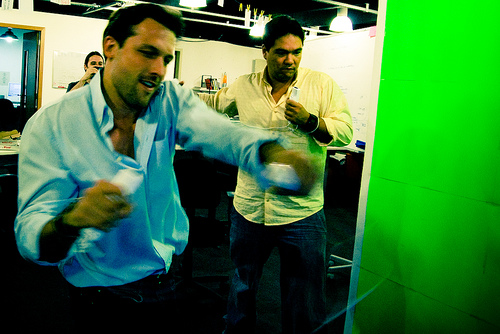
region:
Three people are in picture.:
[46, 15, 371, 237]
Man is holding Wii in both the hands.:
[108, 115, 300, 220]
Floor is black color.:
[332, 254, 348, 331]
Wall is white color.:
[326, 51, 376, 83]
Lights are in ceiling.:
[176, 0, 368, 44]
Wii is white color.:
[99, 156, 309, 216]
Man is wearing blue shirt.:
[39, 89, 209, 259]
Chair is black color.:
[1, 171, 23, 241]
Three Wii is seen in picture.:
[71, 86, 336, 209]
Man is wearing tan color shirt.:
[196, 70, 344, 230]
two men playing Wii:
[12, 7, 372, 329]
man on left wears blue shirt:
[11, 7, 306, 332]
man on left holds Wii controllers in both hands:
[13, 10, 330, 286]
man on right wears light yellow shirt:
[210, 22, 347, 219]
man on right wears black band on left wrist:
[208, 12, 357, 166]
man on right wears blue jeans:
[205, 7, 328, 327]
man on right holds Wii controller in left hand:
[196, 16, 362, 166]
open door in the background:
[0, 0, 55, 127]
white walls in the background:
[10, 13, 374, 163]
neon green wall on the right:
[342, 8, 487, 330]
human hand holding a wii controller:
[253, 136, 315, 198]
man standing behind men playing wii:
[54, 41, 104, 95]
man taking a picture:
[61, 46, 106, 98]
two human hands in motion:
[59, 144, 329, 234]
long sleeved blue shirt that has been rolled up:
[11, 81, 310, 299]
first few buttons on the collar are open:
[96, 113, 158, 180]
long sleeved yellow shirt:
[188, 70, 353, 240]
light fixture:
[328, 11, 355, 41]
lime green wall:
[356, 2, 498, 332]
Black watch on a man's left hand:
[302, 109, 324, 133]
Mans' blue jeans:
[217, 203, 334, 332]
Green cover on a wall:
[358, 2, 495, 332]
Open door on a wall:
[1, 24, 42, 115]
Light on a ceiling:
[327, 5, 354, 38]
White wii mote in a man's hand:
[288, 84, 299, 119]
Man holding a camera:
[79, 52, 107, 87]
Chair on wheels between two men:
[163, 150, 230, 314]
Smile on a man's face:
[125, 72, 167, 99]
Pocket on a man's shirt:
[151, 129, 176, 177]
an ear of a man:
[95, 34, 122, 59]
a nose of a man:
[152, 57, 169, 79]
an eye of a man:
[136, 42, 154, 60]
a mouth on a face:
[132, 76, 162, 92]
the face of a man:
[272, 39, 302, 79]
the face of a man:
[134, 37, 171, 99]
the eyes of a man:
[86, 57, 106, 66]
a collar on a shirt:
[90, 99, 121, 135]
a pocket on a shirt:
[147, 135, 184, 178]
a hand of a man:
[277, 99, 309, 127]